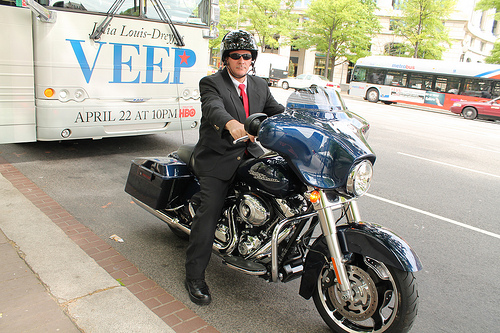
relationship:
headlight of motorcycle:
[325, 142, 388, 197] [123, 83, 423, 330]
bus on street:
[0, 0, 220, 150] [30, 51, 499, 314]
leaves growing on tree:
[279, 2, 400, 91] [277, 12, 417, 82]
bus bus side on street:
[346, 52, 498, 109] [0, 86, 498, 331]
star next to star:
[172, 45, 204, 64] [170, 50, 193, 73]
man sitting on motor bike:
[182, 29, 286, 307] [145, 86, 423, 331]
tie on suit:
[224, 68, 262, 126] [181, 69, 288, 277]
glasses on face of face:
[228, 52, 252, 60] [223, 46, 253, 76]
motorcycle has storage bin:
[113, 72, 431, 331] [122, 140, 205, 215]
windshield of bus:
[49, 0, 227, 27] [2, 0, 211, 142]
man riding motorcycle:
[166, 25, 328, 313] [105, 41, 457, 327]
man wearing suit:
[182, 29, 286, 307] [180, 30, 267, 317]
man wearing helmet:
[182, 29, 286, 307] [220, 27, 258, 59]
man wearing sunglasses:
[182, 29, 286, 307] [221, 44, 259, 64]